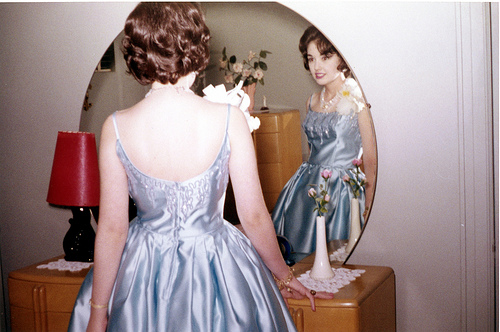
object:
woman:
[85, 2, 333, 331]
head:
[119, 2, 212, 86]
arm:
[227, 105, 290, 274]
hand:
[274, 273, 333, 311]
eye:
[321, 56, 332, 61]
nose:
[313, 59, 325, 71]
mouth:
[314, 72, 327, 79]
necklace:
[319, 79, 349, 111]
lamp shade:
[45, 130, 101, 206]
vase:
[309, 216, 337, 281]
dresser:
[7, 253, 397, 331]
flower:
[250, 68, 265, 81]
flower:
[232, 62, 245, 75]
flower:
[223, 74, 235, 85]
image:
[269, 25, 378, 264]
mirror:
[79, 1, 378, 268]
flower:
[320, 168, 332, 181]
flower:
[307, 187, 319, 198]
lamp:
[46, 129, 101, 262]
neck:
[324, 72, 347, 94]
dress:
[67, 103, 298, 331]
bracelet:
[270, 266, 298, 293]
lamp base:
[62, 206, 99, 263]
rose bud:
[322, 192, 331, 203]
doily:
[294, 266, 367, 295]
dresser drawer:
[7, 278, 93, 312]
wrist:
[275, 267, 297, 283]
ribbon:
[89, 299, 111, 311]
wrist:
[89, 306, 109, 322]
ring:
[309, 289, 317, 295]